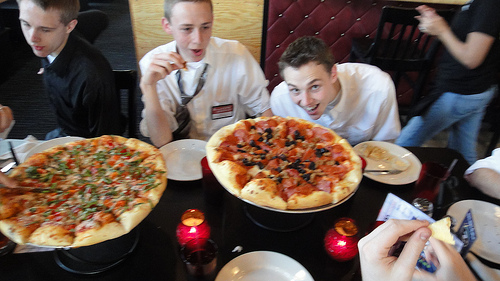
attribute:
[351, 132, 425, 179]
plate — white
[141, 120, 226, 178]
plate — round, white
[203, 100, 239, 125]
name tag — red, rectangular, white, black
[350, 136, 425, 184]
plate — empty, clean, white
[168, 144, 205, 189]
dinner plate — small, clean, white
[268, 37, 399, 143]
man — young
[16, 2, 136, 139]
shirt — black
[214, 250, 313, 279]
plate — empty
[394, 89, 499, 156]
jeans — blue, denim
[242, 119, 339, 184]
olive — black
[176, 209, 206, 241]
candleholder — red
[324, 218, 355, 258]
candleholder — red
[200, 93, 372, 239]
pizza — thick crust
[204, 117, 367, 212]
pizza — hot, fresh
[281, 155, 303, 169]
olives — black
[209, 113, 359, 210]
pizza — sliced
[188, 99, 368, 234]
pizza — freshly baked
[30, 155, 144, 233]
herbs — green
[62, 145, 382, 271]
table — dinner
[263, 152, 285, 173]
topping — pepperoni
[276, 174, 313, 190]
topping — pepperoni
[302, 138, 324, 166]
topping — pepperoni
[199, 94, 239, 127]
tag — name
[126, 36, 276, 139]
shirt — dress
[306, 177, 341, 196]
topping — meat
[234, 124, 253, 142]
topping — meat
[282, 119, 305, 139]
topping — meat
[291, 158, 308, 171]
topping — black olive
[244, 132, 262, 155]
topping — black olive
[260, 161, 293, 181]
topping — black olive